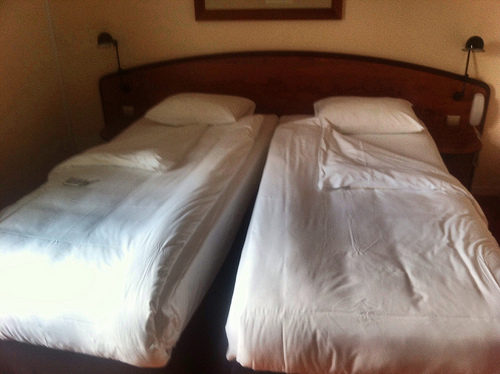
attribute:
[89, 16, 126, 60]
lamp — black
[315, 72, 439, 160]
pillow — white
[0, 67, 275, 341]
bed — here, white, wrinkly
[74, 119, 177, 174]
comforter — white, folded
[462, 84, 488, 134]
phone — white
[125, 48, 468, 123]
headboard — wooden, brown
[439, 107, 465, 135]
lightswitch — here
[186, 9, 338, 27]
picture — framed, hanging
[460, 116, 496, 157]
cord — white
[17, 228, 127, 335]
sun — shinging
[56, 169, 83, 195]
object — white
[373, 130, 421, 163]
sheet — white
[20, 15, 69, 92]
wall — white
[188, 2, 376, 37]
artwork — framed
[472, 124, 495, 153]
telephone — white, here